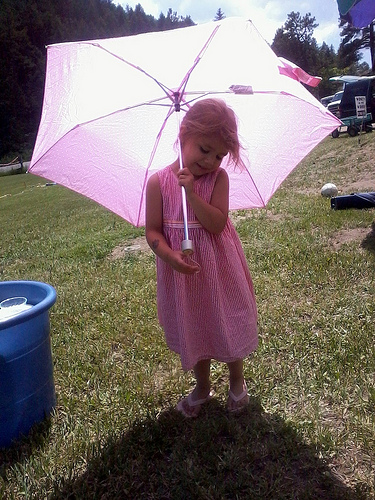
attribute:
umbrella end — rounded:
[42, 41, 57, 50]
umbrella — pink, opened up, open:
[25, 14, 342, 226]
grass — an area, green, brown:
[1, 128, 374, 495]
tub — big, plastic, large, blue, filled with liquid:
[0, 283, 57, 444]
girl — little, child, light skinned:
[147, 97, 254, 416]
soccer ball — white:
[320, 182, 338, 200]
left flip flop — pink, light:
[222, 385, 252, 417]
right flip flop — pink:
[173, 385, 211, 417]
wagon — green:
[332, 112, 374, 140]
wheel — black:
[347, 127, 357, 138]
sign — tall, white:
[352, 94, 368, 132]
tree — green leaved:
[336, 6, 374, 77]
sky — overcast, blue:
[114, 1, 374, 75]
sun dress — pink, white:
[156, 162, 257, 362]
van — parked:
[332, 74, 374, 119]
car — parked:
[329, 93, 348, 120]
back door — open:
[329, 72, 360, 85]